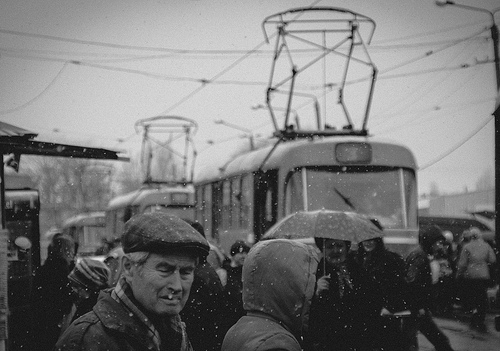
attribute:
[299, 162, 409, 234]
window — large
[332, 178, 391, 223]
wiper — windshield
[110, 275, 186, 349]
scarf — plaid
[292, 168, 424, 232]
window — large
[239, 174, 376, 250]
umbrella — open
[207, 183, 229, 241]
window — large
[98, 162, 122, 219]
tree — tall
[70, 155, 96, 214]
tree — tall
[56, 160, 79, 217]
tree — tall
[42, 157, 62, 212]
tree — tall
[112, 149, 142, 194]
tree — tall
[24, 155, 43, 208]
tree — tall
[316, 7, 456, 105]
lines — electric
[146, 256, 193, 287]
eyes — closed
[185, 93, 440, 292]
train — old, light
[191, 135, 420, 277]
trolley car — top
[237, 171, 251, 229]
window — large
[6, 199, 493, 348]
passengers — wait